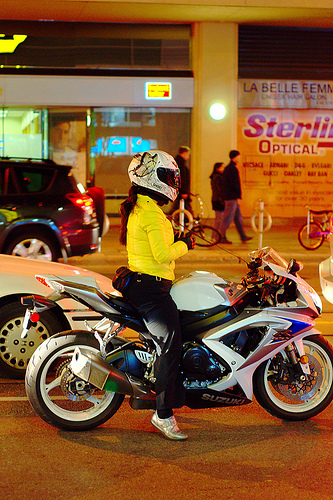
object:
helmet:
[129, 149, 181, 191]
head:
[127, 147, 183, 206]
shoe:
[149, 411, 188, 442]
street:
[0, 372, 332, 498]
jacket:
[124, 192, 188, 281]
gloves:
[185, 234, 196, 250]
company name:
[199, 390, 245, 406]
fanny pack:
[111, 266, 136, 295]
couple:
[208, 146, 250, 247]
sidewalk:
[98, 224, 332, 260]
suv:
[0, 154, 104, 263]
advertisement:
[237, 107, 332, 218]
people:
[212, 162, 225, 239]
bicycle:
[169, 206, 221, 248]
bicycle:
[296, 203, 331, 248]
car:
[0, 253, 122, 379]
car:
[318, 256, 333, 306]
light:
[207, 99, 228, 123]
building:
[1, 1, 332, 228]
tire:
[25, 328, 127, 432]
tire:
[253, 339, 333, 421]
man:
[173, 146, 195, 225]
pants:
[120, 271, 186, 413]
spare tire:
[86, 186, 105, 235]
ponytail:
[119, 187, 138, 245]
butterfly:
[133, 151, 158, 177]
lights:
[96, 139, 102, 153]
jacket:
[172, 155, 191, 200]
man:
[219, 149, 254, 245]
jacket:
[222, 160, 243, 202]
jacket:
[209, 172, 224, 210]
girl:
[126, 151, 192, 446]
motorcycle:
[24, 261, 333, 427]